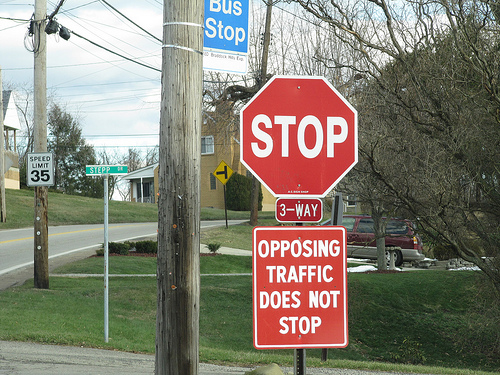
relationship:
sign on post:
[84, 159, 129, 174] [95, 186, 123, 345]